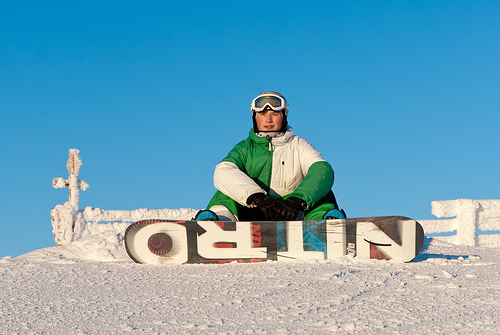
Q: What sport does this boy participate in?
A: Snowboarding.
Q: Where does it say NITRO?
A: Bottom of snowboard.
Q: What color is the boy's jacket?
A: Green and white.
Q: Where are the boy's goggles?
A: His head.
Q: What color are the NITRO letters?
A: White.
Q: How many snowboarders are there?
A: One.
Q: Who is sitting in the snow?
A: A boy.